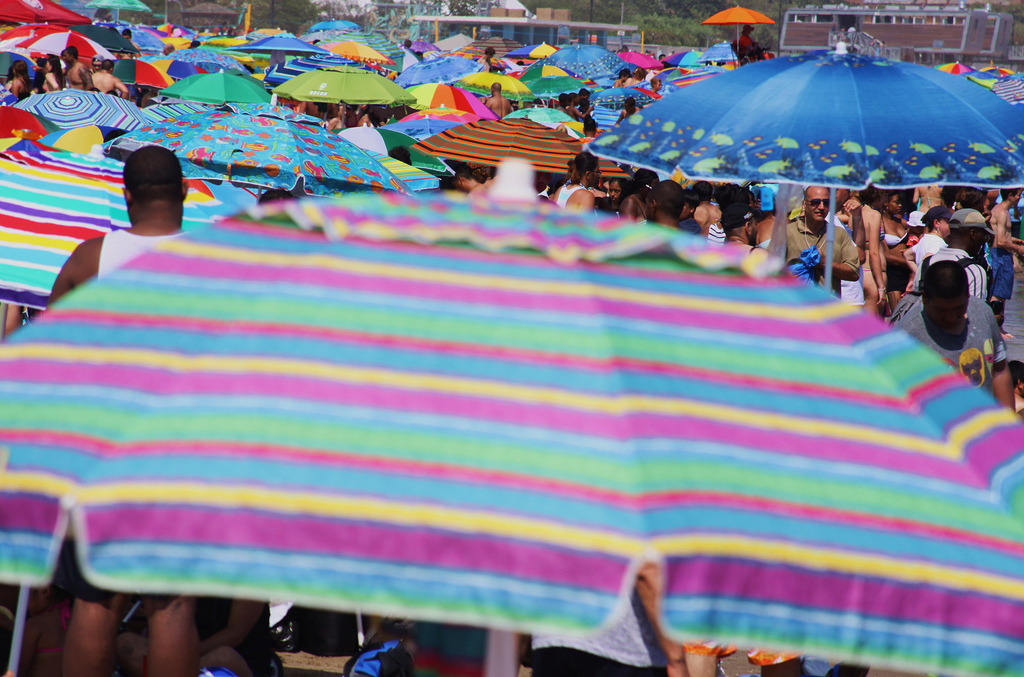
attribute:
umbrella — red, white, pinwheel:
[11, 26, 117, 66]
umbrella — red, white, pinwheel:
[3, 22, 56, 59]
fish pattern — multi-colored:
[119, 98, 407, 192]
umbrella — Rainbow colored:
[399, 81, 506, 127]